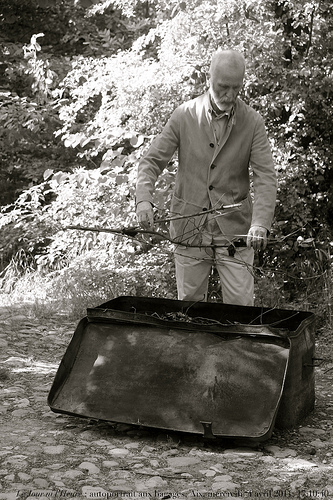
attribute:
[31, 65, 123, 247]
beams — light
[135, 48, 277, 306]
man — standing, elderly, looking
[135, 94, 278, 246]
blazer — button down, button up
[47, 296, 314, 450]
box — metal, black, heavy, brownish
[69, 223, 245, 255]
branches — large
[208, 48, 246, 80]
his hair — gray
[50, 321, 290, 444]
open lid — large, rectangle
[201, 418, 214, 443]
lock — metal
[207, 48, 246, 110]
head — bald, balding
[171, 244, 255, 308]
pants — wrinkled, khaki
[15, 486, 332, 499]
copyright — tiny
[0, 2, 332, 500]
photo — black, white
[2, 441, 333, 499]
ground — cobblestone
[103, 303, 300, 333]
twigs — broken